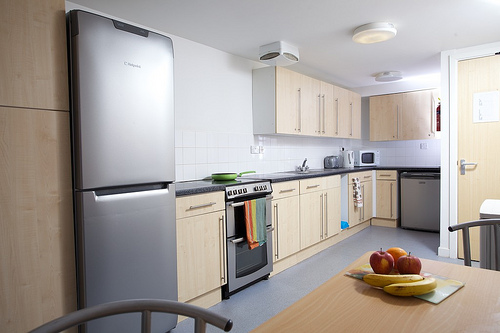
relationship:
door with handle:
[457, 59, 499, 263] [457, 159, 478, 171]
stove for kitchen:
[221, 178, 274, 298] [0, 2, 495, 332]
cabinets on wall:
[251, 66, 310, 139] [63, 0, 349, 180]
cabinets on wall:
[312, 77, 333, 136] [63, 0, 349, 180]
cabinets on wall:
[332, 84, 348, 138] [63, 0, 349, 180]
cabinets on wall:
[370, 87, 432, 139] [350, 75, 439, 168]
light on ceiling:
[352, 20, 399, 46] [71, 0, 499, 92]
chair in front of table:
[447, 216, 498, 263] [229, 245, 496, 331]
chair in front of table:
[11, 295, 230, 332] [229, 245, 496, 331]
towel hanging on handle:
[351, 177, 363, 209] [352, 177, 360, 180]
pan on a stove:
[209, 169, 258, 181] [208, 169, 285, 291]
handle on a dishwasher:
[408, 172, 438, 179] [395, 164, 440, 232]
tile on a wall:
[183, 148, 196, 163] [64, 2, 440, 182]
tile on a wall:
[219, 147, 228, 160] [64, 2, 440, 182]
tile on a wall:
[195, 145, 207, 162] [64, 2, 440, 182]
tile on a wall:
[183, 165, 197, 180] [64, 2, 440, 182]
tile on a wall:
[174, 165, 183, 179] [64, 2, 440, 182]